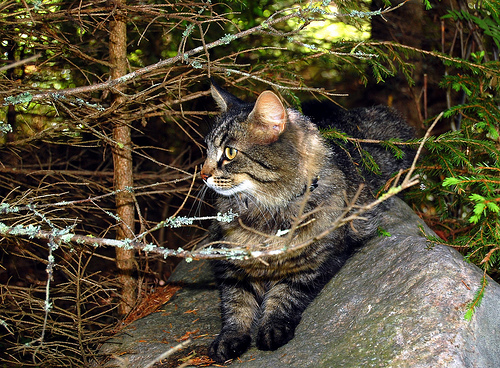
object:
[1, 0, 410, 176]
branches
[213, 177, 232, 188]
whiskers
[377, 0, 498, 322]
tree branches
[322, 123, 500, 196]
needles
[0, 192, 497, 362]
ground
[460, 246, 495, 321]
pine needles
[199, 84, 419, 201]
fur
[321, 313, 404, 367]
moss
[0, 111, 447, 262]
branch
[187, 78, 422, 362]
cat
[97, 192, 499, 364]
rock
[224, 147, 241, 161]
eye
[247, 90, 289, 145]
ear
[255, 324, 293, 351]
paw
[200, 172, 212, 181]
nose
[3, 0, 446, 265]
tree